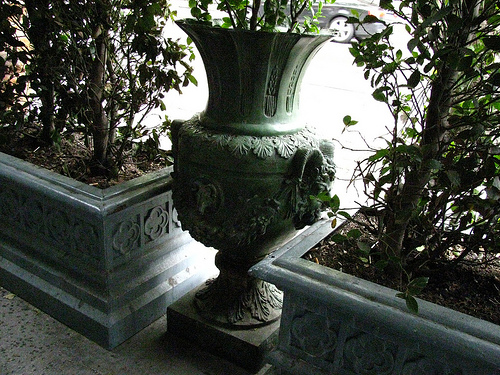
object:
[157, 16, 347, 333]
vase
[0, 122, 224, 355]
planter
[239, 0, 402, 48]
car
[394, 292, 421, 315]
leaf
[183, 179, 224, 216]
head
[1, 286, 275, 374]
floor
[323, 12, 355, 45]
wheel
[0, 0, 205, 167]
branch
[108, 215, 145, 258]
symbol